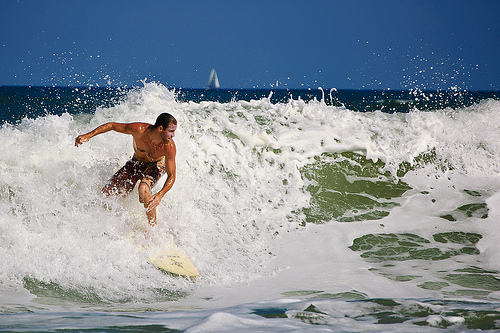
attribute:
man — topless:
[72, 112, 198, 253]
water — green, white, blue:
[1, 86, 499, 331]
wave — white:
[0, 83, 496, 243]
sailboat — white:
[204, 66, 227, 90]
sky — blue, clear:
[1, 0, 499, 89]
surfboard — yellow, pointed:
[78, 185, 231, 284]